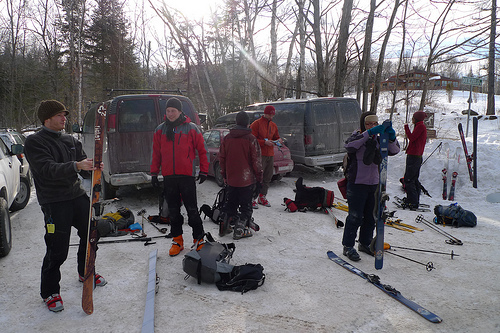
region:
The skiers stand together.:
[21, 86, 471, 331]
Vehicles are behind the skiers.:
[82, 73, 384, 203]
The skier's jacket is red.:
[135, 112, 213, 197]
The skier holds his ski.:
[55, 98, 118, 326]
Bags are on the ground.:
[167, 229, 277, 297]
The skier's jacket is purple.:
[318, 114, 410, 200]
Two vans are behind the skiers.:
[73, 75, 396, 214]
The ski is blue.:
[320, 245, 447, 327]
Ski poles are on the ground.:
[373, 235, 476, 282]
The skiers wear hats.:
[222, 94, 282, 136]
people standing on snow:
[130, 93, 449, 282]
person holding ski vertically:
[342, 112, 404, 268]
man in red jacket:
[146, 94, 205, 189]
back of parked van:
[296, 88, 365, 173]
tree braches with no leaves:
[312, 42, 462, 74]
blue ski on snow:
[317, 244, 442, 329]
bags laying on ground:
[175, 231, 274, 296]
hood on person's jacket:
[220, 121, 257, 151]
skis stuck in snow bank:
[452, 112, 486, 198]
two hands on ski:
[77, 150, 109, 184]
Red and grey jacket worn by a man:
[148, 115, 210, 175]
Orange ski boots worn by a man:
[168, 235, 203, 256]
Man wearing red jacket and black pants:
[150, 99, 210, 256]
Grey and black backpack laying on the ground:
[182, 233, 236, 283]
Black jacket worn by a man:
[20, 125, 85, 200]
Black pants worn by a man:
[38, 195, 99, 295]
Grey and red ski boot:
[38, 291, 63, 311]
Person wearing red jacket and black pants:
[401, 109, 426, 209]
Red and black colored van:
[77, 93, 201, 194]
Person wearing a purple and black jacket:
[343, 112, 400, 260]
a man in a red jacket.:
[145, 83, 215, 258]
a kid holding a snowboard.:
[22, 86, 134, 329]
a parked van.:
[221, 74, 381, 196]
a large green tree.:
[82, 1, 147, 131]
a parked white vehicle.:
[3, 104, 73, 231]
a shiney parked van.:
[199, 83, 376, 179]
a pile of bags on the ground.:
[170, 221, 268, 308]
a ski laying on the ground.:
[323, 243, 454, 332]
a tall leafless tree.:
[74, 1, 93, 131]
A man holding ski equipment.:
[33, 79, 113, 329]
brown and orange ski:
[89, 102, 106, 316]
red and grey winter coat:
[152, 116, 209, 175]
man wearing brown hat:
[28, 98, 104, 305]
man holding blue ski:
[347, 112, 398, 269]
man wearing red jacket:
[403, 112, 429, 212]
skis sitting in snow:
[457, 116, 484, 190]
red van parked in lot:
[96, 93, 204, 194]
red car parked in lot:
[203, 125, 293, 182]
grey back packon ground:
[192, 230, 239, 290]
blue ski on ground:
[329, 249, 438, 328]